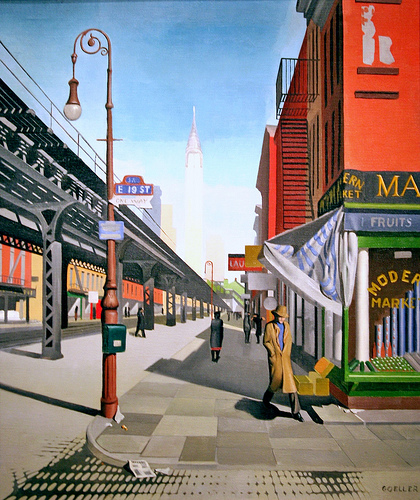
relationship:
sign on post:
[99, 219, 124, 241] [100, 33, 118, 417]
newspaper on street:
[126, 460, 155, 477] [1, 460, 418, 499]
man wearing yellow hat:
[262, 304, 303, 422] [271, 306, 292, 318]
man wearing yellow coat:
[262, 304, 303, 422] [264, 318, 297, 391]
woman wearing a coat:
[209, 310, 223, 364] [208, 316, 223, 346]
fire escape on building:
[282, 57, 315, 229] [276, 2, 418, 373]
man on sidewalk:
[262, 304, 303, 422] [85, 362, 418, 465]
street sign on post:
[110, 176, 152, 197] [100, 33, 118, 417]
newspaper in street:
[126, 460, 155, 477] [1, 460, 418, 499]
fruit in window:
[377, 356, 412, 372] [352, 231, 419, 378]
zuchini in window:
[360, 361, 363, 374] [352, 231, 419, 378]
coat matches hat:
[264, 318, 297, 391] [271, 306, 292, 318]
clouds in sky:
[159, 181, 271, 266] [2, 2, 286, 153]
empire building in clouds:
[186, 103, 203, 263] [159, 181, 271, 266]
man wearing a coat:
[262, 304, 303, 422] [264, 318, 297, 391]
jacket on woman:
[208, 316, 223, 346] [209, 310, 223, 364]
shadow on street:
[26, 440, 357, 499] [1, 460, 418, 499]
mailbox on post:
[102, 325, 125, 353] [100, 33, 118, 417]